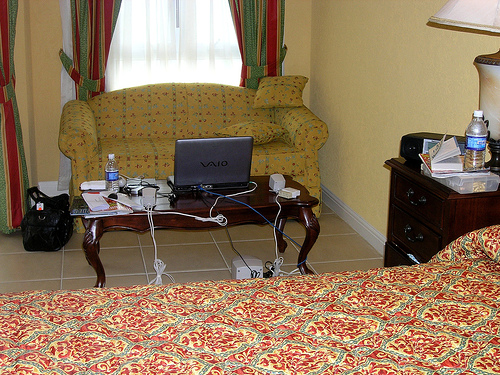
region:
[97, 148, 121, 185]
clear water bottle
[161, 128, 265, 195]
black laptop on brown desk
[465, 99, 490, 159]
clear water bottle with blue label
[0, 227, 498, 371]
The red floral comforter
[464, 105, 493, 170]
The bottle of water on the night stand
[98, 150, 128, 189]
The bottle of water on the coffee table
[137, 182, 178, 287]
The corded phone on the coffee table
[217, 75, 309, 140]
The pillow on the couch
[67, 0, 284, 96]
The yellow couch against the window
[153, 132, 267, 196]
The laptop on the coffee table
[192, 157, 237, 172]
The brand of laptop on the coffee table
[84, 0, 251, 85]
The window behind the couch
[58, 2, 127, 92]
The left curtain behind the couch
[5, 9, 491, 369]
bed, sofa and tables in a room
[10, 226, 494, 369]
busy red bedspread with gray ovals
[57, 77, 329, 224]
yellow sofa with small red and blue pattern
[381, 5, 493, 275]
lamp, book, case and bottle on dark bedside table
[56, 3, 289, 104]
striped curtains over white sheer curtains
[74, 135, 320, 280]
coffee table filled with laptop, wires, devices and magazines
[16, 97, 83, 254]
black case with tag next to sofa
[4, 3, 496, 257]
yellow walls with white trim on bottom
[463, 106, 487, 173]
water bottle with blue label and white cap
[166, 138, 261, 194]
Laptop on a table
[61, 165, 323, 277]
Coffee table with items on it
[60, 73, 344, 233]
Yellow couch in a room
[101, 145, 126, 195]
Water bottle on a table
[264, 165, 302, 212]
Speaker on a table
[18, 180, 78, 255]
Black bag on the floor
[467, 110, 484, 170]
Water bottle on a night stand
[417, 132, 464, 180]
Book on a night stand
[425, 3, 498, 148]
Lamp on a night stand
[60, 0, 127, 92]
Red, green and gold curtain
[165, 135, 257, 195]
Laptop on a coffee table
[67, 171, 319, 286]
Coffee table in front of a couch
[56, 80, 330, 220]
Yellow couch behind a coffee table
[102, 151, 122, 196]
Water bottle on a coffee table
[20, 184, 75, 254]
Black bag on the floor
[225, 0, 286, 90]
Striped curtain on a window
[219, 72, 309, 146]
Two yellow pillows on a couch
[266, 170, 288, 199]
Speaker on a coffee table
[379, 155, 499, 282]
Nightstand next to a bed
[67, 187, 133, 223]
Magazines on a coffee table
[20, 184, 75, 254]
a black piece of luggage with a tag on it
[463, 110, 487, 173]
a bottle of water with a blue label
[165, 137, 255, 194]
an open laptop computer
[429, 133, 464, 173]
a white book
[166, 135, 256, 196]
an open grey laptop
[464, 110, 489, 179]
a plastic water bottle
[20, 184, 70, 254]
a black leather bag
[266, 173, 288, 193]
a grey plastic speaker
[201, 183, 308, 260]
a blue electric cord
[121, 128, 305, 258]
a LAPTOP SITTING ON THE TABLE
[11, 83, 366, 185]
A yellow couch in front of the window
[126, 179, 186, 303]
White cords hanging off of the table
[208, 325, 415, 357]
A red and yellow bedspread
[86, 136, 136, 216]
A bottle of water sitting on the table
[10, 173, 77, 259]
A black bag sitting in the floor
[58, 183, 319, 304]
A brown coffee table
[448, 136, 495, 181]
A bottle water sitting on the nightstand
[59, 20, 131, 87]
Red and green curtains